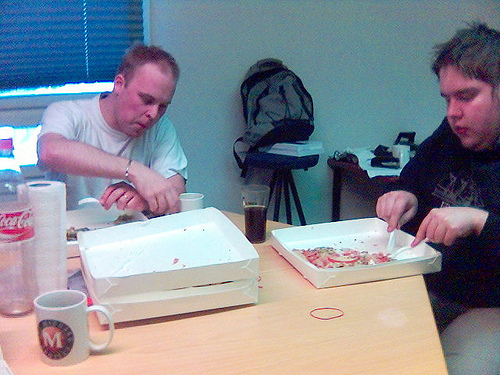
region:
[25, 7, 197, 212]
this is a person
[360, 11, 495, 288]
this is a person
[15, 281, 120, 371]
this is a cup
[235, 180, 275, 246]
this is a glass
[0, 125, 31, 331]
this is a bottle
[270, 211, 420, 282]
this is a box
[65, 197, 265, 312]
this is a box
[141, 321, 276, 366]
this is a table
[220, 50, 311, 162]
this is a bag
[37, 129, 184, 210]
this is a hand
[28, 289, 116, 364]
a white mug on a table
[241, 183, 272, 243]
a glass on a table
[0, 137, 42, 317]
an empty bottle on a table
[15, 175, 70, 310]
a roll of paper sheets on a table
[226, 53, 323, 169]
a back pack laying on a stand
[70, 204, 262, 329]
a stack of empty white boxes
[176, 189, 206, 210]
a white mug on a table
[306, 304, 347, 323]
a rubber band on a table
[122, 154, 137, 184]
a man with a bracelet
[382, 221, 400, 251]
a man using plastic utensils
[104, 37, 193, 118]
man has short hair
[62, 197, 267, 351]
white boxes on table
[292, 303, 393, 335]
red rubber band on table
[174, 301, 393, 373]
table is light brown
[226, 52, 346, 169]
grey backpack near wall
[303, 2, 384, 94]
white wall behind people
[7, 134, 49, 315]
empty bottle of soda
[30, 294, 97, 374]
white mug on table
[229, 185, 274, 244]
clear glass with soda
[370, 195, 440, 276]
boy holds plastic cutlery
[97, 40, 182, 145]
head of a person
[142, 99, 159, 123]
nose of a person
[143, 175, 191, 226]
hand of a person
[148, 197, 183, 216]
fingers of a person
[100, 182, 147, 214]
fingers of a person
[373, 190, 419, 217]
fingers of a person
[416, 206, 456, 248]
fingers of a person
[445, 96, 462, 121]
nose of a person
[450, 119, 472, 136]
mouth of a person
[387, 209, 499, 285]
man is holding a fork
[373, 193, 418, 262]
man is holding a knife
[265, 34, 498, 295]
man is eating a pizza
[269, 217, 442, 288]
pizza is in a box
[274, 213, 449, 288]
box is on the table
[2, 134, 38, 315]
the coca cola bottle is empty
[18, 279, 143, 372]
the mug is on the table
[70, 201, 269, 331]
the box is on top of another box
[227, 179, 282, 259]
the glass is on the table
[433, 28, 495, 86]
the hair is brown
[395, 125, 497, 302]
the shirt is black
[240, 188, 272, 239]
clear glass with a beverage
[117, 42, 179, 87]
the hair is brown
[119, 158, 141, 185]
bracelet on the wrist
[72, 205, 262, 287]
the box is white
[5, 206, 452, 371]
the table top is wood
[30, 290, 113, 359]
white coffee mug with a logo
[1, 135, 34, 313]
clear bottle with red and white label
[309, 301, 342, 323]
the band is red